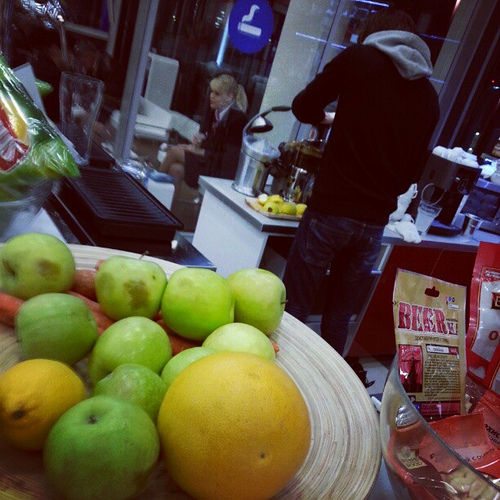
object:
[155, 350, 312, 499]
orange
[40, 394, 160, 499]
apple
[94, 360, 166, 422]
apple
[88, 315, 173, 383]
apple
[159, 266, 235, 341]
apple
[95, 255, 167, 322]
apple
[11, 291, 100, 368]
apple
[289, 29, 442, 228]
sweatshirt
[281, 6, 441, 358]
man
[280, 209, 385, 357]
jeans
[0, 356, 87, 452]
lemon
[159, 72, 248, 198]
woman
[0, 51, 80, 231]
lays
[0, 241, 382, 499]
plate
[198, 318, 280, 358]
fruit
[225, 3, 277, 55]
smoking sign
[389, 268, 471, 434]
snacks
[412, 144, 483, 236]
beverage machine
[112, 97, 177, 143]
bench